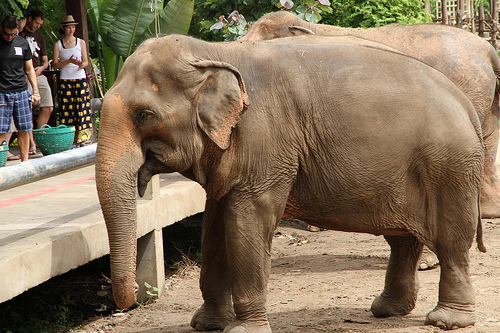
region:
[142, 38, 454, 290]
an elephant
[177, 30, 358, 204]
an elephant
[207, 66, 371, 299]
an elephant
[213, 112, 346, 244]
an elephant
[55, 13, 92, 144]
woman next to man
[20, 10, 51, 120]
man standing next to woman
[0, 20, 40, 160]
man near green bowl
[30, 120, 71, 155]
plastic green bowl near people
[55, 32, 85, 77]
white tank top on woman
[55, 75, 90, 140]
black and yellow pants on woman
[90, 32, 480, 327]
large gray elephant on ground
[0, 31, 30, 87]
black shirt on man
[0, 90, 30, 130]
blue plaid shorts on man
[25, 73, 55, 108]
khaki shorts on man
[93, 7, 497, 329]
Two elephants are in the picture.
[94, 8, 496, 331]
The elephants are brown.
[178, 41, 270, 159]
The elephants have small ears.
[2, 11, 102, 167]
People are in the background.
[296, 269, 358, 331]
The ground is made of dirt.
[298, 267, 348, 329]
The ground is brown.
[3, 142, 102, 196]
A metal fence pole.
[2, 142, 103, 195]
The pole is gray.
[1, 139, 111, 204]
The pole is made of metal.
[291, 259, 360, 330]
The dirt is brown.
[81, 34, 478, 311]
a big elephant is standing near the people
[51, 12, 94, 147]
a cap on the girls head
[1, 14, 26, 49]
a man wearing specks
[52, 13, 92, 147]
a girl standing near the plant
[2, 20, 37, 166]
a man wearing black colour t-shirt and blue colour shorts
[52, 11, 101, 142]
a girl wearing skirt and t-shirt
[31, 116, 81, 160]
a green colour basket kept on the floor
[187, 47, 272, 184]
ear of the elephant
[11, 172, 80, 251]
cement floor in front of the elephant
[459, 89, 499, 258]
a tail of the elephant